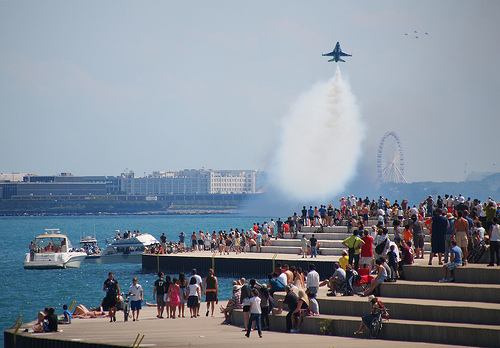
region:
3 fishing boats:
[28, 226, 155, 273]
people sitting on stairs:
[224, 278, 341, 346]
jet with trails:
[282, 38, 376, 198]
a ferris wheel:
[370, 120, 430, 190]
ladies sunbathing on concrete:
[66, 296, 115, 338]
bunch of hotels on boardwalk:
[1, 161, 277, 216]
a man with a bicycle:
[116, 270, 147, 320]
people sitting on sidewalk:
[20, 301, 75, 341]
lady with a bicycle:
[355, 291, 413, 346]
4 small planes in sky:
[395, 20, 450, 50]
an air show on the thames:
[9, 2, 496, 344]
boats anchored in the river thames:
[16, 217, 170, 284]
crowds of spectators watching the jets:
[21, 190, 497, 340]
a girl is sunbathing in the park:
[69, 300, 107, 324]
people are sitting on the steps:
[236, 250, 398, 331]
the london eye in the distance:
[370, 127, 411, 198]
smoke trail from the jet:
[261, 40, 365, 207]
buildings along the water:
[8, 166, 285, 216]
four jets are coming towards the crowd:
[401, 27, 434, 44]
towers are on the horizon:
[458, 155, 498, 185]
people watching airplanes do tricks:
[201, 19, 454, 311]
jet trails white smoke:
[273, 34, 364, 194]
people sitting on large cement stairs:
[256, 271, 466, 344]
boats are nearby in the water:
[29, 215, 149, 275]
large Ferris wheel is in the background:
[368, 126, 418, 199]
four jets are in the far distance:
[393, 22, 439, 58]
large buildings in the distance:
[11, 157, 271, 214]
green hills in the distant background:
[322, 161, 491, 197]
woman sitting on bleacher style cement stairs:
[356, 292, 410, 338]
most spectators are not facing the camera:
[201, 180, 484, 270]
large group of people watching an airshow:
[0, 2, 499, 345]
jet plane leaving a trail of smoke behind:
[270, 29, 368, 201]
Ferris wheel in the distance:
[365, 124, 422, 196]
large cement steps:
[402, 281, 499, 343]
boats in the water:
[15, 219, 163, 273]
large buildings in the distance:
[1, 124, 278, 224]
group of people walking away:
[144, 262, 221, 333]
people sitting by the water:
[5, 284, 83, 341]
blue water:
[4, 272, 86, 302]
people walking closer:
[96, 267, 149, 336]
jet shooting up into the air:
[233, 34, 391, 199]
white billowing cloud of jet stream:
[254, 79, 402, 199]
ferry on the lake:
[22, 223, 85, 277]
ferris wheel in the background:
[367, 129, 413, 199]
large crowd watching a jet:
[231, 189, 491, 316]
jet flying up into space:
[251, 25, 386, 198]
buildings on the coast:
[13, 161, 260, 210]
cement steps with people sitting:
[354, 247, 471, 334]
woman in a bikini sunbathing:
[71, 300, 116, 319]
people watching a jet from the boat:
[27, 207, 167, 272]